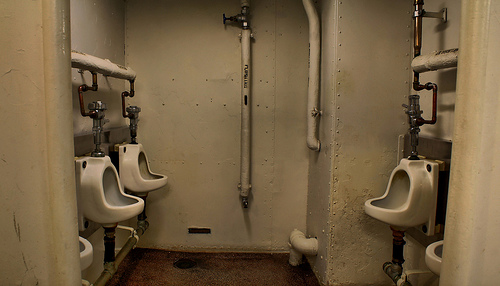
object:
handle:
[218, 9, 251, 26]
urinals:
[65, 143, 161, 267]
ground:
[350, 136, 391, 188]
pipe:
[221, 0, 254, 207]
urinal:
[363, 155, 435, 231]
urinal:
[70, 154, 144, 226]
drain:
[171, 258, 203, 269]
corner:
[324, 0, 346, 285]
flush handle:
[400, 104, 410, 109]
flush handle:
[101, 118, 111, 123]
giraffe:
[397, 0, 454, 157]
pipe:
[101, 225, 117, 270]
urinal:
[77, 232, 96, 273]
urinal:
[115, 141, 169, 194]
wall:
[0, 0, 500, 286]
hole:
[187, 227, 213, 236]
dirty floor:
[106, 247, 319, 286]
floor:
[106, 243, 324, 286]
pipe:
[399, 0, 448, 131]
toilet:
[359, 161, 440, 231]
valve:
[215, 9, 257, 32]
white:
[311, 42, 319, 71]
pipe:
[304, 0, 325, 150]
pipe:
[288, 228, 318, 269]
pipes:
[76, 68, 107, 156]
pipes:
[120, 79, 141, 144]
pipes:
[70, 52, 138, 80]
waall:
[0, 0, 500, 286]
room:
[0, 0, 500, 286]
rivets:
[326, 0, 340, 286]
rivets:
[143, 74, 284, 84]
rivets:
[151, 101, 278, 108]